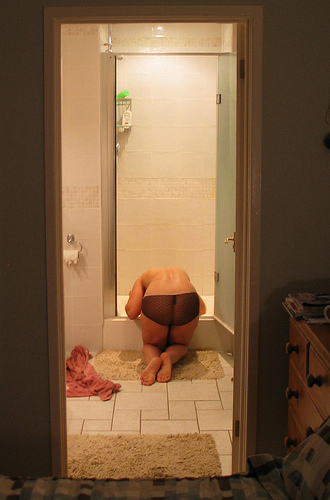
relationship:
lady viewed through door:
[125, 265, 207, 387] [44, 9, 264, 495]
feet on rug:
[136, 349, 175, 388] [93, 336, 227, 383]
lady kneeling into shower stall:
[125, 265, 207, 387] [100, 49, 206, 322]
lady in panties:
[125, 265, 207, 387] [138, 286, 208, 328]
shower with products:
[114, 53, 125, 65] [117, 82, 133, 134]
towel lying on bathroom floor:
[65, 345, 122, 401] [64, 348, 232, 475]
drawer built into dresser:
[286, 316, 308, 380] [280, 300, 315, 454]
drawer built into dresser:
[305, 341, 319, 418] [280, 300, 315, 454]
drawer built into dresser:
[286, 358, 319, 439] [280, 300, 315, 454]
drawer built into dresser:
[284, 404, 305, 459] [280, 300, 315, 454]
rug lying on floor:
[66, 430, 223, 480] [65, 351, 234, 477]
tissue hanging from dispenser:
[63, 249, 80, 266] [66, 232, 83, 252]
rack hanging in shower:
[116, 96, 132, 132] [106, 22, 234, 350]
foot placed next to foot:
[138, 354, 161, 385] [154, 351, 172, 383]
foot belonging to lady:
[138, 354, 161, 385] [124, 264, 207, 385]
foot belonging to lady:
[154, 351, 172, 383] [124, 264, 207, 385]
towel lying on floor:
[65, 345, 122, 401] [65, 351, 234, 477]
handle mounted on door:
[224, 231, 237, 252] [230, 21, 247, 474]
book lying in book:
[281, 291, 328, 320] [281, 291, 328, 320]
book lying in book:
[280, 301, 303, 320] [281, 291, 328, 320]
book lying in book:
[303, 315, 318, 325] [281, 291, 328, 320]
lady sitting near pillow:
[125, 265, 207, 387] [276, 414, 306, 498]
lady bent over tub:
[125, 265, 207, 387] [103, 291, 220, 351]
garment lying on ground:
[66, 345, 121, 402] [63, 351, 232, 475]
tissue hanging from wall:
[63, 249, 80, 266] [59, 23, 104, 353]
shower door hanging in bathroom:
[213, 51, 236, 336] [60, 22, 238, 478]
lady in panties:
[114, 258, 221, 392] [137, 289, 202, 326]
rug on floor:
[66, 430, 223, 480] [170, 387, 214, 423]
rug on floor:
[66, 430, 223, 480] [143, 392, 216, 419]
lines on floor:
[159, 384, 175, 420] [122, 391, 201, 424]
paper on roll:
[63, 244, 79, 268] [66, 230, 82, 254]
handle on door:
[224, 231, 237, 252] [222, 62, 250, 470]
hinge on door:
[230, 418, 245, 437] [219, 23, 257, 470]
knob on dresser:
[280, 339, 301, 357] [277, 310, 314, 445]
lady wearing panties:
[125, 265, 207, 387] [141, 292, 200, 327]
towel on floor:
[65, 341, 126, 408] [65, 351, 234, 477]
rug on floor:
[94, 345, 225, 382] [65, 351, 234, 477]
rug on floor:
[66, 427, 225, 480] [65, 351, 234, 477]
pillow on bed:
[284, 429, 327, 499] [1, 426, 323, 496]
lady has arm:
[125, 265, 207, 387] [127, 270, 147, 319]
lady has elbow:
[125, 265, 207, 387] [122, 298, 141, 317]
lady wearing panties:
[125, 265, 207, 387] [139, 287, 206, 325]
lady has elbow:
[125, 265, 207, 387] [196, 295, 208, 313]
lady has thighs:
[125, 265, 207, 387] [142, 305, 199, 344]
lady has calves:
[125, 265, 207, 387] [142, 339, 193, 358]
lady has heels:
[125, 265, 207, 387] [146, 348, 177, 358]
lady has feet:
[125, 265, 207, 387] [136, 349, 175, 388]